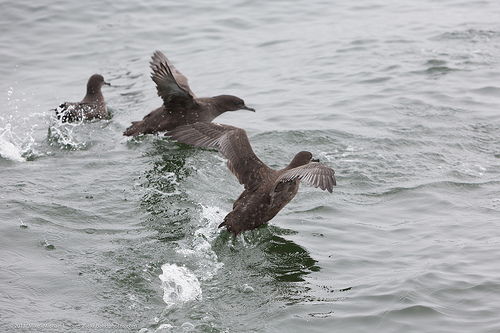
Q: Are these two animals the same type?
A: Yes, all the animals are birds.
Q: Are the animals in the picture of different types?
A: No, all the animals are birds.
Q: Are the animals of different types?
A: No, all the animals are birds.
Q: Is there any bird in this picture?
A: Yes, there is a bird.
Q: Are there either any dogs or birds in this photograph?
A: Yes, there is a bird.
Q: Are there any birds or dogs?
A: Yes, there is a bird.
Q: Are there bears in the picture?
A: No, there are no bears.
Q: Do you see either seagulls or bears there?
A: No, there are no bears or seagulls.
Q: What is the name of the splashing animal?
A: The animal is a bird.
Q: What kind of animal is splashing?
A: The animal is a bird.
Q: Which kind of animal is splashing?
A: The animal is a bird.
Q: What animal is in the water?
A: The bird is in the water.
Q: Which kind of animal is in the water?
A: The animal is a bird.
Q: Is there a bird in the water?
A: Yes, there is a bird in the water.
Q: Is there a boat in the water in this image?
A: No, there is a bird in the water.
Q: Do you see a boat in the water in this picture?
A: No, there is a bird in the water.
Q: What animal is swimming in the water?
A: The bird is swimming in the water.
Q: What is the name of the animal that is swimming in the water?
A: The animal is a bird.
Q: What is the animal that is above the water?
A: The animal is a bird.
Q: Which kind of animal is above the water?
A: The animal is a bird.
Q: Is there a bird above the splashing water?
A: Yes, there is a bird above the water.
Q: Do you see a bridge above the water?
A: No, there is a bird above the water.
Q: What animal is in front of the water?
A: The bird is in front of the water.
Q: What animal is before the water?
A: The bird is in front of the water.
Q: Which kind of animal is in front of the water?
A: The animal is a bird.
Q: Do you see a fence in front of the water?
A: No, there is a bird in front of the water.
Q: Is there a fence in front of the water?
A: No, there is a bird in front of the water.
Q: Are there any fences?
A: No, there are no fences.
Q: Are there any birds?
A: Yes, there is a bird.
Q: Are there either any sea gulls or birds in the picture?
A: Yes, there is a bird.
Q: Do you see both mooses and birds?
A: No, there is a bird but no mooses.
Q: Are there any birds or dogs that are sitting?
A: Yes, the bird is sitting.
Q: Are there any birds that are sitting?
A: Yes, there is a bird that is sitting.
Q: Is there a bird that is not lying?
A: Yes, there is a bird that is sitting.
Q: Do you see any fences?
A: No, there are no fences.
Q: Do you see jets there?
A: No, there are no jets.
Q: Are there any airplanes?
A: No, there are no airplanes.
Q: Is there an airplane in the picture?
A: No, there are no airplanes.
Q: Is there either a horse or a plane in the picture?
A: No, there are no airplanes or horses.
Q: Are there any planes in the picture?
A: No, there are no planes.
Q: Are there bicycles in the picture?
A: No, there are no bicycles.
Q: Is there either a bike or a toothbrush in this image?
A: No, there are no bikes or toothbrushes.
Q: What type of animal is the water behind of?
A: The water is behind the bird.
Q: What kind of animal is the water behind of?
A: The water is behind the bird.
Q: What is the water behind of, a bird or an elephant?
A: The water is behind a bird.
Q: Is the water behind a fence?
A: No, the water is behind the bird.